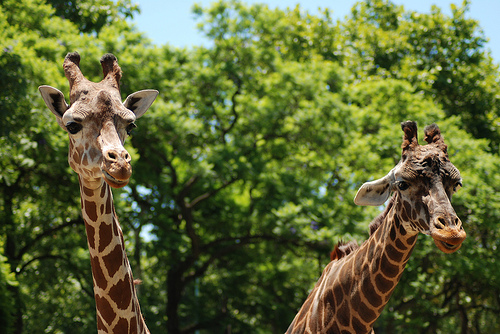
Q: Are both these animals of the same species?
A: Yes, all the animals are giraffes.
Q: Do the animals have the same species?
A: Yes, all the animals are giraffes.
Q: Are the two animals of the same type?
A: Yes, all the animals are giraffes.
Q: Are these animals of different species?
A: No, all the animals are giraffes.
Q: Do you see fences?
A: No, there are no fences.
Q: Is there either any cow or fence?
A: No, there are no fences or cows.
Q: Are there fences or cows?
A: No, there are no fences or cows.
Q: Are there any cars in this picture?
A: No, there are no cars.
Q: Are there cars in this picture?
A: No, there are no cars.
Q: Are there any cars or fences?
A: No, there are no cars or fences.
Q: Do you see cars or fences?
A: No, there are no cars or fences.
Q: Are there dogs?
A: No, there are no dogs.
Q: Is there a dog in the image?
A: No, there are no dogs.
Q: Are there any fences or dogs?
A: No, there are no dogs or fences.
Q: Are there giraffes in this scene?
A: Yes, there is a giraffe.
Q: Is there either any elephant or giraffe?
A: Yes, there is a giraffe.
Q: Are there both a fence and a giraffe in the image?
A: No, there is a giraffe but no fences.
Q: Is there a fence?
A: No, there are no fences.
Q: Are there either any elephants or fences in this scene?
A: No, there are no fences or elephants.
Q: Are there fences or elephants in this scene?
A: No, there are no fences or elephants.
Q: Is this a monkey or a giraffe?
A: This is a giraffe.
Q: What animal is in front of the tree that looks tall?
A: The giraffe is in front of the tree.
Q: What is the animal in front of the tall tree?
A: The animal is a giraffe.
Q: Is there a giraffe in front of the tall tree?
A: Yes, there is a giraffe in front of the tree.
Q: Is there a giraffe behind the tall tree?
A: No, the giraffe is in front of the tree.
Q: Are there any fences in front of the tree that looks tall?
A: No, there is a giraffe in front of the tree.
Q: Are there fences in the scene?
A: No, there are no fences.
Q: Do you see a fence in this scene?
A: No, there are no fences.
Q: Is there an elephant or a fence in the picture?
A: No, there are no fences or elephants.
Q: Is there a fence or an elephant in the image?
A: No, there are no fences or elephants.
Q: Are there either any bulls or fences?
A: No, there are no fences or bulls.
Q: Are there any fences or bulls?
A: No, there are no fences or bulls.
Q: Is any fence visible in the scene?
A: No, there are no fences.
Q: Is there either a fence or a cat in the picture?
A: No, there are no fences or cats.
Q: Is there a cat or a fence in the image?
A: No, there are no fences or cats.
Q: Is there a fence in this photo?
A: No, there are no fences.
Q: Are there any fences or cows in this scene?
A: No, there are no fences or cows.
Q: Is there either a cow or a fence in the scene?
A: No, there are no fences or cows.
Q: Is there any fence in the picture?
A: No, there are no fences.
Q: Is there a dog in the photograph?
A: No, there are no dogs.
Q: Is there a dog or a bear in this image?
A: No, there are no dogs or bears.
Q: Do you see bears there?
A: No, there are no bears.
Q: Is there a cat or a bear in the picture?
A: No, there are no bears or cats.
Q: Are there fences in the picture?
A: No, there are no fences.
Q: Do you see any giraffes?
A: Yes, there is a giraffe.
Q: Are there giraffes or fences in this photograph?
A: Yes, there is a giraffe.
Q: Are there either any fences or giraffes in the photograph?
A: Yes, there is a giraffe.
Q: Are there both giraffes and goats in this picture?
A: No, there is a giraffe but no goats.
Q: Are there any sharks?
A: No, there are no sharks.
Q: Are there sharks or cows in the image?
A: No, there are no sharks or cows.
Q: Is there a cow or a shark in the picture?
A: No, there are no sharks or cows.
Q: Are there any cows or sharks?
A: No, there are no sharks or cows.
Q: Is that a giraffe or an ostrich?
A: That is a giraffe.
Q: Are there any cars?
A: No, there are no cars.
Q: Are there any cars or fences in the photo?
A: No, there are no cars or fences.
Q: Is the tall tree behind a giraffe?
A: Yes, the tree is behind a giraffe.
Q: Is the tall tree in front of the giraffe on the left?
A: No, the tree is behind the giraffe.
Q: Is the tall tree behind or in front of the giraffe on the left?
A: The tree is behind the giraffe.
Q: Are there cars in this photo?
A: No, there are no cars.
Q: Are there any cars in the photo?
A: No, there are no cars.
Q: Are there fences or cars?
A: No, there are no cars or fences.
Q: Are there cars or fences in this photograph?
A: No, there are no cars or fences.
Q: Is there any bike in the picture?
A: No, there are no bikes.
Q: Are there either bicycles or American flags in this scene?
A: No, there are no bicycles or American flags.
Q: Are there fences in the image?
A: No, there are no fences.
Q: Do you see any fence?
A: No, there are no fences.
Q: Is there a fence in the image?
A: No, there are no fences.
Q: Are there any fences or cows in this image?
A: No, there are no fences or cows.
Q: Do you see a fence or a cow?
A: No, there are no fences or cows.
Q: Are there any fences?
A: No, there are no fences.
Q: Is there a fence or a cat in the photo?
A: No, there are no fences or cats.